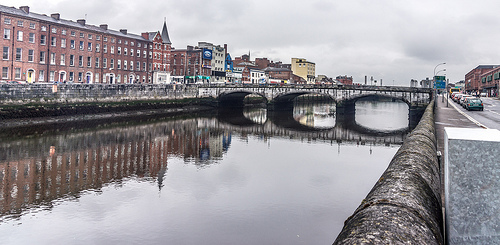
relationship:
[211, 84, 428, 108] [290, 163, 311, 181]
bridge over water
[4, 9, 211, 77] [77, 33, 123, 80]
building has windows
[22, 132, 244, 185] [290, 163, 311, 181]
reflection in water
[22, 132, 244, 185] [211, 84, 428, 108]
reflection of bridge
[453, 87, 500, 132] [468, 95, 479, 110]
line of cars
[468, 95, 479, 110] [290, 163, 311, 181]
cars by water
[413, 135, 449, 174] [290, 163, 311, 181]
pipe by water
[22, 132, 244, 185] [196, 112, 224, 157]
reflection of 2nd building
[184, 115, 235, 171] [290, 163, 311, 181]
reflection in water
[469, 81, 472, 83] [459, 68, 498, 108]
row of buildings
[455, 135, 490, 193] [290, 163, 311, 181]
slab by water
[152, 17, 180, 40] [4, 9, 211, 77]
roof on building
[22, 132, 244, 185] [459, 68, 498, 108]
reflection of buildings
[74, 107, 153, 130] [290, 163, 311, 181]
side of water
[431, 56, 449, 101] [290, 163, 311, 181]
street lights by water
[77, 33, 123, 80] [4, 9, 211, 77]
windows in building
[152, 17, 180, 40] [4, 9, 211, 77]
roof of building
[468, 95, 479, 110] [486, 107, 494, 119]
cars on road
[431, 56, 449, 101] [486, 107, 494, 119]
street lights over road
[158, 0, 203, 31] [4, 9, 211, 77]
steeple on building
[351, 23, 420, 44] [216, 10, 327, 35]
cloud in sky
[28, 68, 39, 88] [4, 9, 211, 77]
doorway of building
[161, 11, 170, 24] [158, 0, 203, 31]
top of steeple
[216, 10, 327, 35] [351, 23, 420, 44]
sky has cloud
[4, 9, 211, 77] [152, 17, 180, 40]
building has roof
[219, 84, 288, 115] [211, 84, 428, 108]
opening under bridge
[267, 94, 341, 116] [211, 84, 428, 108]
opening under bridge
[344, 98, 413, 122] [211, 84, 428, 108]
opening under bridge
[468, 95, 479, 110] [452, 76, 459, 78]
cars on right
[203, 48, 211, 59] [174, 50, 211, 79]
sign on building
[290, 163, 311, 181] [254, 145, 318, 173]
water in middle